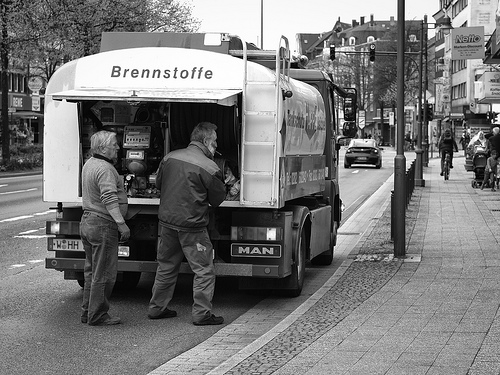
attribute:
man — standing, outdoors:
[148, 122, 230, 325]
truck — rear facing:
[43, 41, 359, 299]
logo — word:
[109, 63, 214, 81]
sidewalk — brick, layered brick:
[204, 147, 499, 373]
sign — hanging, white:
[448, 25, 487, 61]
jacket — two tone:
[153, 142, 226, 229]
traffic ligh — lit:
[365, 41, 377, 62]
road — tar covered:
[0, 144, 397, 374]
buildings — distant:
[280, 15, 425, 144]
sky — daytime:
[146, 0, 446, 59]